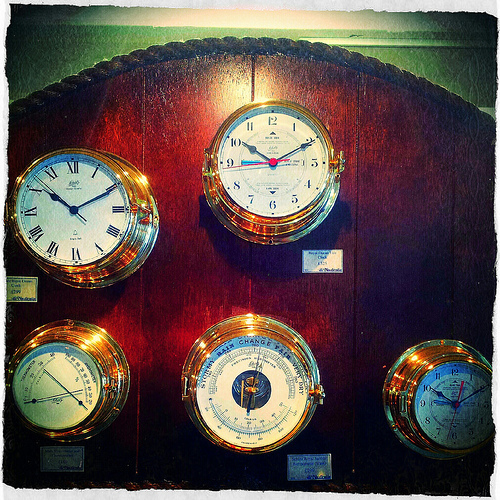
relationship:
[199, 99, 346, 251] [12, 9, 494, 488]
clock on wall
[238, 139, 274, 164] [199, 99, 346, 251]
hand on clock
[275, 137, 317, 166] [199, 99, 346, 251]
hand on clock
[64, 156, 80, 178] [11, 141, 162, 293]
roman numeral on clock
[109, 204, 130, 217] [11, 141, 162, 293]
roman numeral on clock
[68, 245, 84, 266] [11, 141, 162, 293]
roman numeral on clock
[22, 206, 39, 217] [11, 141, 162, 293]
roman numeral on clock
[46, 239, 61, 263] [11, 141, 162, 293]
roman numeral on clock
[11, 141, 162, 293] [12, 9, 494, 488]
clock on wall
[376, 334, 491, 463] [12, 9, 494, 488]
clock on wall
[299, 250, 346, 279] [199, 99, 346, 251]
card below clock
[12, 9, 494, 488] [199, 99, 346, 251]
wall behind clock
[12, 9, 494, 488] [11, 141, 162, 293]
wall behind clock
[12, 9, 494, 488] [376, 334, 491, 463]
wall behind clock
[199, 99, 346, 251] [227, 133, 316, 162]
clock shows time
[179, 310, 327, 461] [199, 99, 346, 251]
barometer below clock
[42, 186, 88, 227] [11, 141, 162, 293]
hour hand on clock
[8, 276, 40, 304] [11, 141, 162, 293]
sign underneath clock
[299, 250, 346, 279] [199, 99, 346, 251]
card underneath clock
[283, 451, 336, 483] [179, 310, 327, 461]
card under barometer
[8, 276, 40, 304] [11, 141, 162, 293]
sign under clock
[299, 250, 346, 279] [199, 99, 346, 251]
card under clock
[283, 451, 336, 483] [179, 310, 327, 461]
card undernath barometer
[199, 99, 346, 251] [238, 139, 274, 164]
clock has hand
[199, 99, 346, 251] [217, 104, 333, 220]
clock has glass face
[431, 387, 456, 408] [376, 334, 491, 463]
hand on clock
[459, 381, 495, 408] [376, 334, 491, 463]
hand on clock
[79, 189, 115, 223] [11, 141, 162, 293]
minute hand on clock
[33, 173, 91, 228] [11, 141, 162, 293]
second hand on clock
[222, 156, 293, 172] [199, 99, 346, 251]
second hand on clock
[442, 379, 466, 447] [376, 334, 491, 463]
second hand on clock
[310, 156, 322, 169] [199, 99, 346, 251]
number 3 on clock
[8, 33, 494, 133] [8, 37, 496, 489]
rope edge on wood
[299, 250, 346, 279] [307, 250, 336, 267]
card has words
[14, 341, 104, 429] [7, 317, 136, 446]
gauge has frame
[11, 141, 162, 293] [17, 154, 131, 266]
clock has face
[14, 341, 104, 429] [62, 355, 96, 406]
gauge has arch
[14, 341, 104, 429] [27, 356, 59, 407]
gauge has arch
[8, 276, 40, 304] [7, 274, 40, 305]
sign has border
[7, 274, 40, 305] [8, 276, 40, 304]
border inside sign